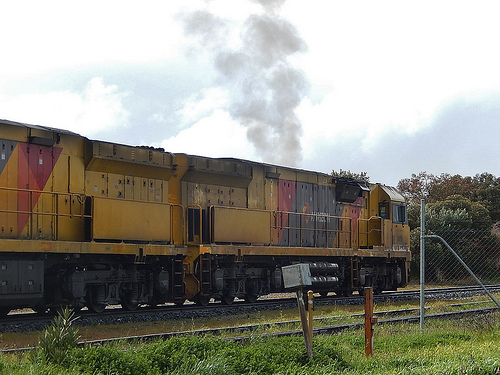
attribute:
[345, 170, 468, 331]
fence — chain link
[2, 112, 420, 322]
train — yellow